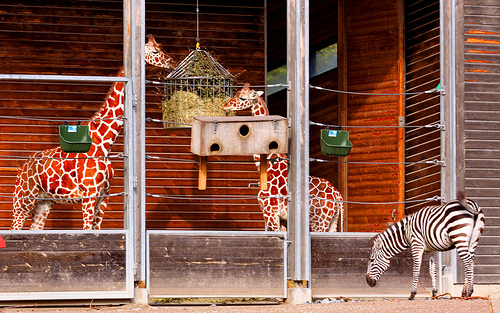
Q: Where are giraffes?
A: In enclosure.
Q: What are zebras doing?
A: Standing.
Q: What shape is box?
A: Rectangle.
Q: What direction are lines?
A: Horizontal.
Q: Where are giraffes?
A: At feeder.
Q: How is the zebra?
A: Bent.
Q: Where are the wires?
A: Across wall.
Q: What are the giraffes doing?
A: Eating.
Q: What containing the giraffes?
A: A wire cage.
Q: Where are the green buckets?
A: Hanging from the wire.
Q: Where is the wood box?
A: Hanging from the wire.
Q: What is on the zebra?
A: Stripes.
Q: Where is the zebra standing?
A: Near the giraffes.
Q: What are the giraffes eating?
A: Hay.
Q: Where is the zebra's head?
A: Near the ground.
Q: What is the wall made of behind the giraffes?
A: Wood.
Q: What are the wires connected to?
A: Metal poles.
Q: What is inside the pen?
A: Giraffes.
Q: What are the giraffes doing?
A: Eating.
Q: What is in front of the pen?
A: A zebra.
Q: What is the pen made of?
A: Metal and wood.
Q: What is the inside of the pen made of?
A: Wood.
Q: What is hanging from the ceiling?
A: A cage with giraffe food.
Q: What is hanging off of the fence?
A: A metal box.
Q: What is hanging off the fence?
A: Green containers.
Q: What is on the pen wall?
A: A window.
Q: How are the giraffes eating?
A: Through a tiny cage of food.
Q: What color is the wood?
A: Brown.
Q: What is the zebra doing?
A: Grazing for food.